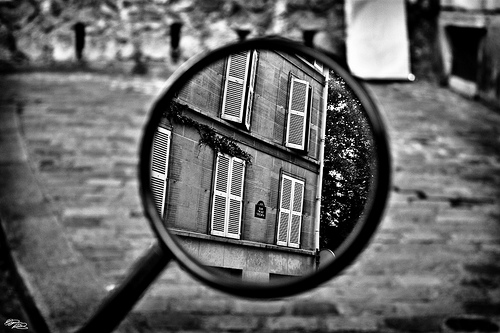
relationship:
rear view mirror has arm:
[138, 37, 392, 300] [64, 245, 172, 332]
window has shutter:
[210, 152, 246, 238] [210, 151, 232, 237]